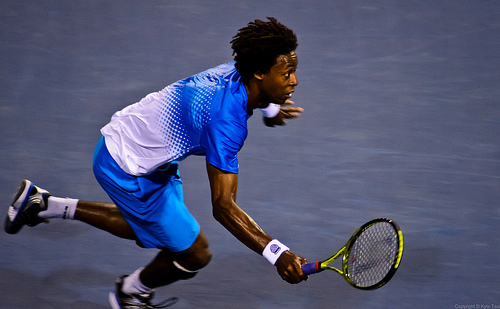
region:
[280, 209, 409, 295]
black and yellow tennis racket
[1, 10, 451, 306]
man swinging a tennis racket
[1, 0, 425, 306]
a man running across a tennis court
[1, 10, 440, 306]
man about to hit a tennis ball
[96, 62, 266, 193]
blue and white shirt on the man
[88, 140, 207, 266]
blue shorts on the man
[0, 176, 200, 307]
black, white, and blue tennis shoes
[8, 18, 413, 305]
a tennis player hitting the ball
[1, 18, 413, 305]
tennis player attempting to catch up to the ball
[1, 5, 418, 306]
tennis player running across the court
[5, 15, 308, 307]
a man is playing tennis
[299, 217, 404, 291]
a tennis racket with a blue handle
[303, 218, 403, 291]
a black and yellow tennis racket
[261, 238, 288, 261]
a white wristband with a blue symbol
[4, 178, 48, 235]
a black, white, blue, and silver shoe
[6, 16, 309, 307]
a man wearing blue shorts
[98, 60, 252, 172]
a white and blue shirt on a man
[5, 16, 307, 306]
a man has dark hair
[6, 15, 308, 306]
a man with muscular legs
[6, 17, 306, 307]
a tennis player with muscular arms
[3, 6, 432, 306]
man playing tennis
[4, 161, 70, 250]
foot lifted off the ground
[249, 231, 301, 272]
thick white and blue wristband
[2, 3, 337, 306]
man wearing white and blue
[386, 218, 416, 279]
yellow line on top of the racket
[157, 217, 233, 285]
knee is bent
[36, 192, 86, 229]
whtie and black sock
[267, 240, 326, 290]
fingers wrapped around the handle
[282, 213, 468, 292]
yellow and black tennis racket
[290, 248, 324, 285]
blue and red handle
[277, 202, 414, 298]
A tennis racket in a player's hand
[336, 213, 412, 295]
The head of a tennis racket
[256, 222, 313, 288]
A wristband on a tennis player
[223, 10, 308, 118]
A man's head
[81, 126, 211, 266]
A pair of blue shorts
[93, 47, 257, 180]
A blue and white shirt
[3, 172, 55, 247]
A tennis shoe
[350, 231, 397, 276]
The strings of a tennis racket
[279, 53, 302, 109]
A man's profile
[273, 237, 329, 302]
A hand gripping a racket handle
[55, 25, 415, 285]
man on the tennis court.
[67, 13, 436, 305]
Man playing tennis.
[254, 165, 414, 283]
Man's arm and hand with racket.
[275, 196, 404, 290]
Racket in the man's hand.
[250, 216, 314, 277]
Wrist band on the man.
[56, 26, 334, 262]
Man in bright blue shorts.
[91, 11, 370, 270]
Man in a tennis outfit.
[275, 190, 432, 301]
Yellow and black racket.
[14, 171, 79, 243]
Shoes and socks on the man.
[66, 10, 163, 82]
Blue tennis court.